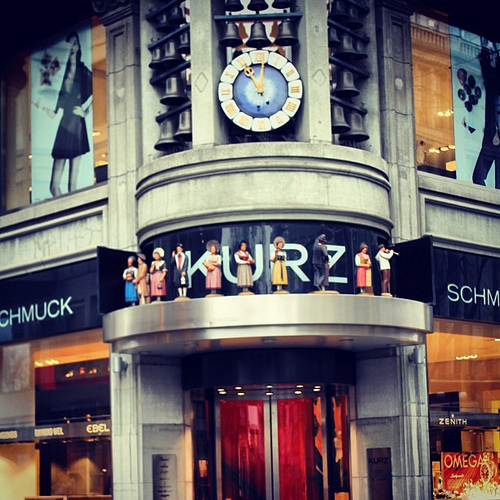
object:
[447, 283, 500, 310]
sign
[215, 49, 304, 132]
clock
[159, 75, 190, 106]
bells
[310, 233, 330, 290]
statues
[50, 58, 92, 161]
dress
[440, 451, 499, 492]
perfume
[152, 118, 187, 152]
bells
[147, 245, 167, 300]
statue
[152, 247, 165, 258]
hat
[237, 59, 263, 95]
clock hand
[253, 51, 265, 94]
clock hand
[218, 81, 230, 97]
numbers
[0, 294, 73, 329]
sign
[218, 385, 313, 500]
curtains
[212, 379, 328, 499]
entrance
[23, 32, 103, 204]
picture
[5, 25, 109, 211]
window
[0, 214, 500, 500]
picture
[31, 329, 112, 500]
window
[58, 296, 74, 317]
writing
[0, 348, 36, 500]
wall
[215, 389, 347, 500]
door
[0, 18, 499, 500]
store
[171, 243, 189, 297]
figurines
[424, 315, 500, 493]
window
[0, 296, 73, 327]
logo's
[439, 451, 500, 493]
poster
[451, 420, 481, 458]
woman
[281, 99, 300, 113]
numerals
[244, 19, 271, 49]
bells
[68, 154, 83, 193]
legs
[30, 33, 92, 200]
woman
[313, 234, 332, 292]
figurine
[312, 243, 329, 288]
coat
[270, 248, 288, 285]
dress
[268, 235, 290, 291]
figurine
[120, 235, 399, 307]
awing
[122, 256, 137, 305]
figurine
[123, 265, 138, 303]
dress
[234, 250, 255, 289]
dress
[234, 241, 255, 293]
figurine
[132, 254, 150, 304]
figurine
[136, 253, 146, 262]
fedora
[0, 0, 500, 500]
building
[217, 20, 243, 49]
toys